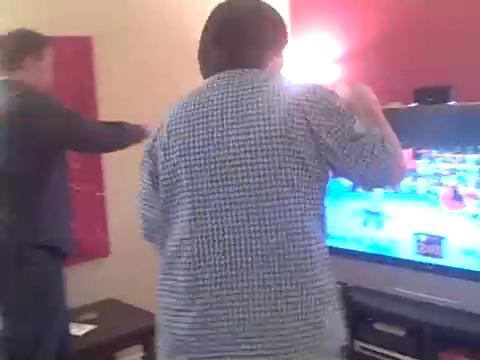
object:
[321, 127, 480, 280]
screen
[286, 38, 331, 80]
light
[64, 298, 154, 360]
table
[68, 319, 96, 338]
paper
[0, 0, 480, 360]
picture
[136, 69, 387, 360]
shirt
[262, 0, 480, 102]
wall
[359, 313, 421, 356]
box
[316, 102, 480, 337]
tv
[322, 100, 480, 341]
television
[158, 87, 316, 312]
back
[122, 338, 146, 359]
ground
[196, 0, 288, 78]
hair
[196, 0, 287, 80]
head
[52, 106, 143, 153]
arm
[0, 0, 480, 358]
room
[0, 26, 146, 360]
men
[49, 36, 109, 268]
artwork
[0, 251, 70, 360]
pants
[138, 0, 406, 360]
person